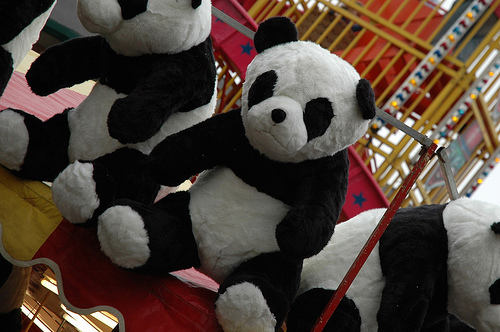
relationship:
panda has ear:
[97, 15, 375, 331] [250, 14, 301, 56]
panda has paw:
[97, 15, 375, 331] [271, 211, 331, 261]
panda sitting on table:
[2, 2, 219, 228] [2, 68, 287, 330]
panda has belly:
[97, 15, 375, 331] [187, 159, 288, 286]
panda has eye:
[97, 15, 375, 331] [301, 95, 336, 148]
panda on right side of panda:
[288, 193, 500, 332] [97, 15, 375, 331]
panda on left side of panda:
[2, 2, 219, 228] [97, 15, 375, 331]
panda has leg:
[97, 15, 375, 331] [96, 185, 200, 281]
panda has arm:
[97, 15, 375, 331] [273, 151, 352, 261]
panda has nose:
[97, 15, 375, 331] [269, 107, 289, 127]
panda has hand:
[97, 15, 375, 331] [150, 138, 195, 193]